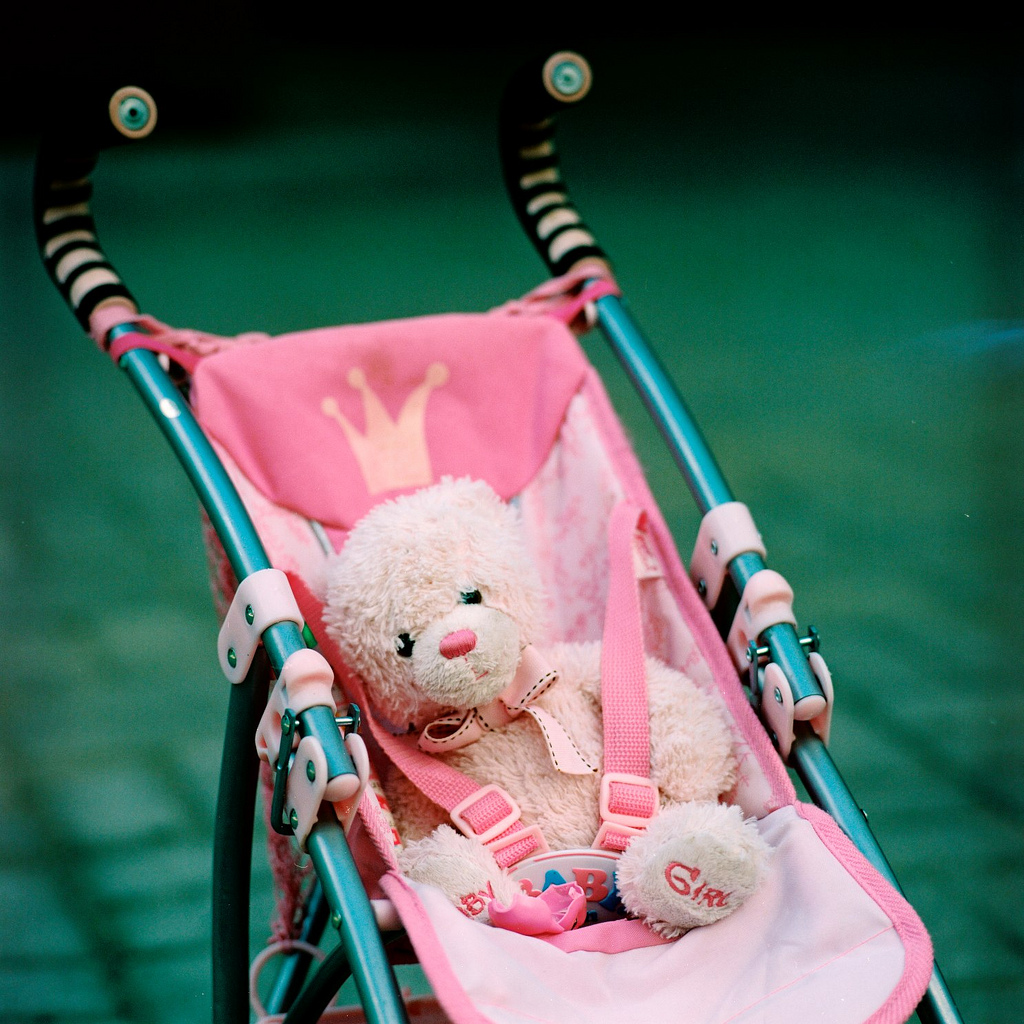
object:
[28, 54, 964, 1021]
stroller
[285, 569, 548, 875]
strap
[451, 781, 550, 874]
buckle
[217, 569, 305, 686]
clamp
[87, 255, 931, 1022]
cloth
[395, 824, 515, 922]
foot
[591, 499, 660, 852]
straps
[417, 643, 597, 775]
bow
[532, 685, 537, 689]
dots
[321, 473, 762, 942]
"baby girl"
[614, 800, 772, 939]
feet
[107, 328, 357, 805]
bars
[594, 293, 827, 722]
bars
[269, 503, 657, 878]
straps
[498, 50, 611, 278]
handle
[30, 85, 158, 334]
handle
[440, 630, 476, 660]
nose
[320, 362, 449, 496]
crown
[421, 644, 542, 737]
neck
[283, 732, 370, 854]
screws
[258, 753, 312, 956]
chain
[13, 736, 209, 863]
squares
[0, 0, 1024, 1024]
ground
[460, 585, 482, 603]
button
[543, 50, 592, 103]
circle